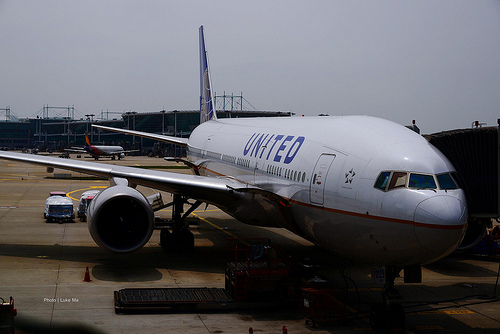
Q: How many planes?
A: Two.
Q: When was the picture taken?
A: Daytime.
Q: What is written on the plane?
A: UNITED.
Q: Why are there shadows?
A: Sun is out.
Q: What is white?
A: Plane.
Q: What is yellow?
A: Circles on the ground.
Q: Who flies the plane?
A: Pilot.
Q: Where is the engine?
A: On the wing.